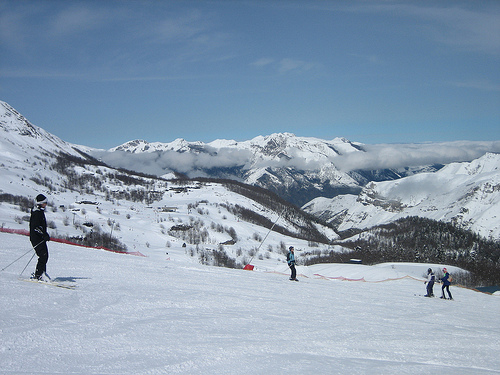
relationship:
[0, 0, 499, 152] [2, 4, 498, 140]
cloud in sky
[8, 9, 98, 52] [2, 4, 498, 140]
cloud in sky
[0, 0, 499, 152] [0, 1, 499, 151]
cloud are in blue sky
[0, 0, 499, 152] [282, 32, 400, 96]
cloud are in sky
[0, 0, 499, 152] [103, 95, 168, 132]
cloud are in blue sky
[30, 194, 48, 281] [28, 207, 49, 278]
person wearing skiing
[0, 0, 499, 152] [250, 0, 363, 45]
cloud in blue sky